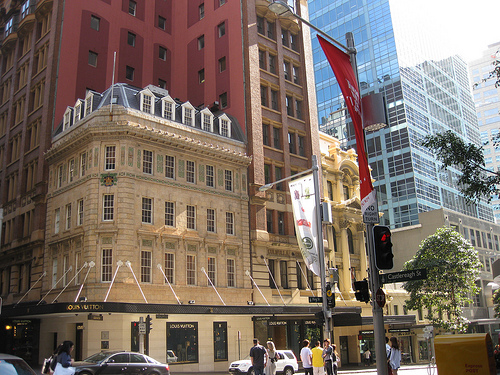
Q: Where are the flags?
A: On the poles.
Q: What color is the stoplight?
A: Red.